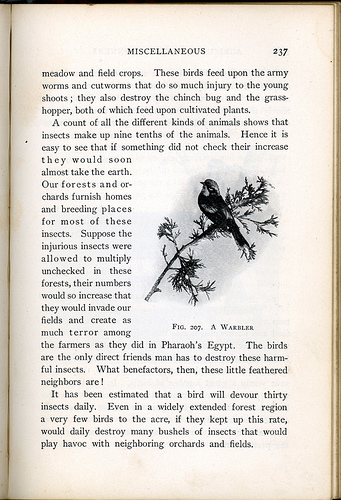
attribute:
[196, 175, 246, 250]
bird — drawing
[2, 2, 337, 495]
book — printed